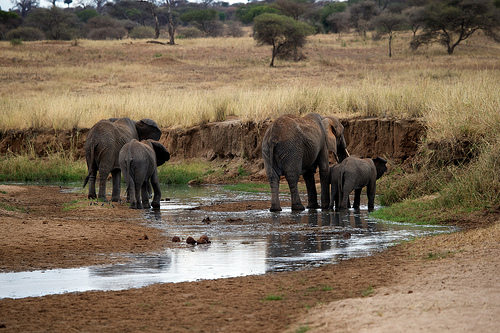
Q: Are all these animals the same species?
A: Yes, all the animals are elephants.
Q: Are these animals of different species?
A: No, all the animals are elephants.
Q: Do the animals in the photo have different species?
A: No, all the animals are elephants.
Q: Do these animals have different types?
A: No, all the animals are elephants.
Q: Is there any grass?
A: Yes, there is grass.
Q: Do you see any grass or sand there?
A: Yes, there is grass.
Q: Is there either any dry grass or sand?
A: Yes, there is dry grass.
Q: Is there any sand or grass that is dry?
A: Yes, the grass is dry.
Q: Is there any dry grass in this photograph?
A: Yes, there is dry grass.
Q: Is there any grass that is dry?
A: Yes, there is grass that is dry.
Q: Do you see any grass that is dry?
A: Yes, there is grass that is dry.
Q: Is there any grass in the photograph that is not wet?
A: Yes, there is dry grass.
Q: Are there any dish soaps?
A: No, there are no dish soaps.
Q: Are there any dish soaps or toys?
A: No, there are no dish soaps or toys.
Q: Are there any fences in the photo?
A: No, there are no fences.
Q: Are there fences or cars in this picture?
A: No, there are no fences or cars.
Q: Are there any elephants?
A: Yes, there are elephants.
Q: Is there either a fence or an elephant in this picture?
A: Yes, there are elephants.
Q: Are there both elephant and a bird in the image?
A: No, there are elephants but no birds.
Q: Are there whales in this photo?
A: No, there are no whales.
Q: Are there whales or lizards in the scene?
A: No, there are no whales or lizards.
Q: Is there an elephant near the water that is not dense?
A: Yes, there are elephants near the water.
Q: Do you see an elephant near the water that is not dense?
A: Yes, there are elephants near the water.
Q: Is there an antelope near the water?
A: No, there are elephants near the water.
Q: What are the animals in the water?
A: The animals are elephants.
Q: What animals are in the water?
A: The animals are elephants.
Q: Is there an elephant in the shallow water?
A: Yes, there are elephants in the water.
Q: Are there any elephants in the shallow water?
A: Yes, there are elephants in the water.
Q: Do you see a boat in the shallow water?
A: No, there are elephants in the water.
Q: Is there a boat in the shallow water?
A: No, there are elephants in the water.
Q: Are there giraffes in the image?
A: No, there are no giraffes.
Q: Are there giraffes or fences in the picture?
A: No, there are no giraffes or fences.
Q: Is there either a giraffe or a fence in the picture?
A: No, there are no giraffes or fences.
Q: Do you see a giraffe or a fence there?
A: No, there are no giraffes or fences.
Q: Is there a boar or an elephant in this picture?
A: Yes, there is an elephant.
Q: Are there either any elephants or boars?
A: Yes, there is an elephant.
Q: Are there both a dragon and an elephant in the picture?
A: No, there is an elephant but no dragons.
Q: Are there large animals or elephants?
A: Yes, there is a large elephant.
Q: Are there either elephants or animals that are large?
A: Yes, the elephant is large.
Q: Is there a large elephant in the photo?
A: Yes, there is a large elephant.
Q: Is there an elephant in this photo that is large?
A: Yes, there is an elephant that is large.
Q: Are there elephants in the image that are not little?
A: Yes, there is a large elephant.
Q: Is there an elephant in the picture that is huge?
A: Yes, there is a huge elephant.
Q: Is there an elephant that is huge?
A: Yes, there is an elephant that is huge.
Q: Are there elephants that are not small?
A: Yes, there is a huge elephant.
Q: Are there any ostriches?
A: No, there are no ostriches.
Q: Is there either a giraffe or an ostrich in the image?
A: No, there are no ostriches or giraffes.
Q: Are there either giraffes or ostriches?
A: No, there are no ostriches or giraffes.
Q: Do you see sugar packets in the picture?
A: No, there are no sugar packets.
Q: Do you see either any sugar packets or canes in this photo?
A: No, there are no sugar packets or canes.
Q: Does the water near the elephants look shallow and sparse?
A: Yes, the water is shallow and sparse.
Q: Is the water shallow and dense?
A: No, the water is shallow but sparse.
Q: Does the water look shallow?
A: Yes, the water is shallow.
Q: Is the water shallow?
A: Yes, the water is shallow.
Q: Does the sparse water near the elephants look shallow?
A: Yes, the water is shallow.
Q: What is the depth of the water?
A: The water is shallow.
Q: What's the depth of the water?
A: The water is shallow.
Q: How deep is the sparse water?
A: The water is shallow.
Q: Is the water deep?
A: No, the water is shallow.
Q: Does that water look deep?
A: No, the water is shallow.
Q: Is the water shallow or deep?
A: The water is shallow.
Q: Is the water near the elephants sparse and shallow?
A: Yes, the water is sparse and shallow.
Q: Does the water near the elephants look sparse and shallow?
A: Yes, the water is sparse and shallow.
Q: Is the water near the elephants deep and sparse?
A: No, the water is sparse but shallow.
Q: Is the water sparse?
A: Yes, the water is sparse.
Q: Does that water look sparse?
A: Yes, the water is sparse.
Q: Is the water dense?
A: No, the water is sparse.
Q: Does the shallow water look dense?
A: No, the water is sparse.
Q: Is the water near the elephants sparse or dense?
A: The water is sparse.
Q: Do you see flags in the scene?
A: No, there are no flags.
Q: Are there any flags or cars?
A: No, there are no flags or cars.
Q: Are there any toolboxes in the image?
A: No, there are no toolboxes.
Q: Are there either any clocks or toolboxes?
A: No, there are no toolboxes or clocks.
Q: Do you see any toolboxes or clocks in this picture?
A: No, there are no toolboxes or clocks.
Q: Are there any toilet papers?
A: No, there are no toilet papers.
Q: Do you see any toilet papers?
A: No, there are no toilet papers.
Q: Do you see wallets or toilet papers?
A: No, there are no toilet papers or wallets.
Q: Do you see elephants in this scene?
A: Yes, there is an elephant.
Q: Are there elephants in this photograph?
A: Yes, there is an elephant.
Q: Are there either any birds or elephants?
A: Yes, there is an elephant.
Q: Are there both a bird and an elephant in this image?
A: No, there is an elephant but no birds.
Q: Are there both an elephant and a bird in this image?
A: No, there is an elephant but no birds.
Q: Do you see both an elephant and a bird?
A: No, there is an elephant but no birds.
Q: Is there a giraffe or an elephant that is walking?
A: Yes, the elephant is walking.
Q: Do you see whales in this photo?
A: No, there are no whales.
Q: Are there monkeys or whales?
A: No, there are no whales or monkeys.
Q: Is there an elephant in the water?
A: Yes, there is an elephant in the water.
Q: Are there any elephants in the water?
A: Yes, there is an elephant in the water.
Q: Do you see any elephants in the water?
A: Yes, there is an elephant in the water.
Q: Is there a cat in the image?
A: No, there are no cats.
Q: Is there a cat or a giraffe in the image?
A: No, there are no cats or giraffes.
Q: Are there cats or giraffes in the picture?
A: No, there are no cats or giraffes.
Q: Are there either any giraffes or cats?
A: No, there are no cats or giraffes.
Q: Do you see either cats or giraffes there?
A: No, there are no cats or giraffes.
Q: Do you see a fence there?
A: No, there are no fences.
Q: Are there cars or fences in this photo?
A: No, there are no fences or cars.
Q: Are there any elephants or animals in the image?
A: Yes, there is an elephant.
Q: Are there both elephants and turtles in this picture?
A: No, there is an elephant but no turtles.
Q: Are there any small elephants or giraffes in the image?
A: Yes, there is a small elephant.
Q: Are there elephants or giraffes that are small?
A: Yes, the elephant is small.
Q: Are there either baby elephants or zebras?
A: Yes, there is a baby elephant.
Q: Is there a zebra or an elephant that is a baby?
A: Yes, the elephant is a baby.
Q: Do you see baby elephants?
A: Yes, there is a baby elephant.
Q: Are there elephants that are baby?
A: Yes, there is an elephant that is a baby.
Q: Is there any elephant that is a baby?
A: Yes, there is an elephant that is a baby.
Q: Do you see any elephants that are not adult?
A: Yes, there is an baby elephant.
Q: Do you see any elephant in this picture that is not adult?
A: Yes, there is an baby elephant.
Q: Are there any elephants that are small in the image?
A: Yes, there is a small elephant.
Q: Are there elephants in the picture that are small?
A: Yes, there is an elephant that is small.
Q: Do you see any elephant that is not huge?
A: Yes, there is a small elephant.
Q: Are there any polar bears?
A: No, there are no polar bears.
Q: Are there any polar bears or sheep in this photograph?
A: No, there are no polar bears or sheep.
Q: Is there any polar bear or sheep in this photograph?
A: No, there are no polar bears or sheep.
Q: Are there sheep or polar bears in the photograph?
A: No, there are no polar bears or sheep.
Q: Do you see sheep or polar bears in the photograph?
A: No, there are no polar bears or sheep.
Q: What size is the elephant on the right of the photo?
A: The elephant is small.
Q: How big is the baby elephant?
A: The elephant is small.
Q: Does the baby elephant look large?
A: No, the elephant is small.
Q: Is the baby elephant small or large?
A: The elephant is small.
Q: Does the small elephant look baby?
A: Yes, the elephant is a baby.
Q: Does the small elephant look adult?
A: No, the elephant is a baby.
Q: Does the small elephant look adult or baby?
A: The elephant is a baby.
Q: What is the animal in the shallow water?
A: The animal is an elephant.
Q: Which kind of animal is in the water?
A: The animal is an elephant.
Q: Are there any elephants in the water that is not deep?
A: Yes, there is an elephant in the water.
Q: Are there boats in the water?
A: No, there is an elephant in the water.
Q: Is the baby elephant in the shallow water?
A: Yes, the elephant is in the water.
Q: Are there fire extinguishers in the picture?
A: No, there are no fire extinguishers.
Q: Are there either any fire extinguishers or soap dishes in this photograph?
A: No, there are no fire extinguishers or soap dishes.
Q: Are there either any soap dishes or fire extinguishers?
A: No, there are no fire extinguishers or soap dishes.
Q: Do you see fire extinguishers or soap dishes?
A: No, there are no fire extinguishers or soap dishes.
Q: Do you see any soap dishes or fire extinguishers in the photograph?
A: No, there are no fire extinguishers or soap dishes.